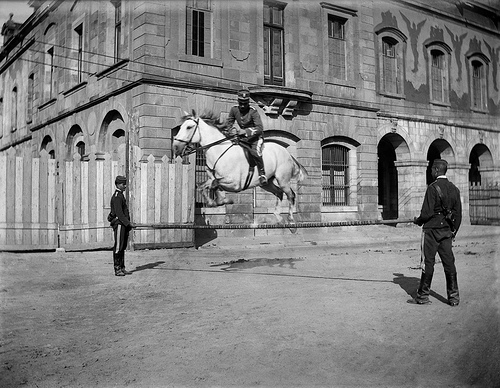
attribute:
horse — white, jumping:
[172, 109, 308, 233]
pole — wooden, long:
[131, 217, 424, 230]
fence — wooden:
[1, 152, 196, 256]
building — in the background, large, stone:
[0, 0, 499, 250]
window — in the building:
[194, 147, 228, 204]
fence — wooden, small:
[469, 182, 500, 224]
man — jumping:
[221, 92, 265, 185]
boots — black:
[406, 286, 458, 305]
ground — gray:
[0, 234, 499, 387]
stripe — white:
[114, 224, 123, 255]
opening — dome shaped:
[427, 139, 457, 185]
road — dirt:
[0, 234, 497, 387]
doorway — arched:
[470, 142, 493, 186]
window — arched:
[382, 33, 401, 95]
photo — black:
[0, 1, 496, 386]